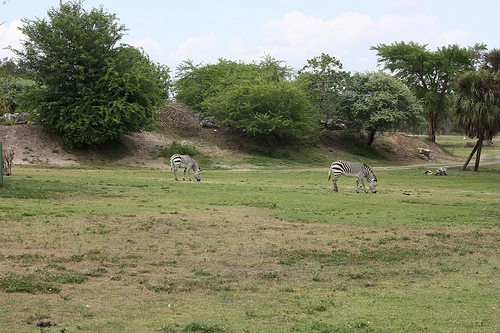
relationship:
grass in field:
[331, 267, 376, 328] [2, 130, 497, 330]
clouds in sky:
[264, 15, 463, 53] [0, 2, 499, 77]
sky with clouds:
[0, 0, 500, 96] [246, 8, 474, 54]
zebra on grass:
[327, 159, 378, 193] [199, 180, 413, 227]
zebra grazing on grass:
[165, 147, 204, 183] [199, 180, 413, 227]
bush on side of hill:
[2, 4, 179, 156] [49, 40, 308, 189]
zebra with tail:
[311, 145, 396, 210] [326, 163, 335, 183]